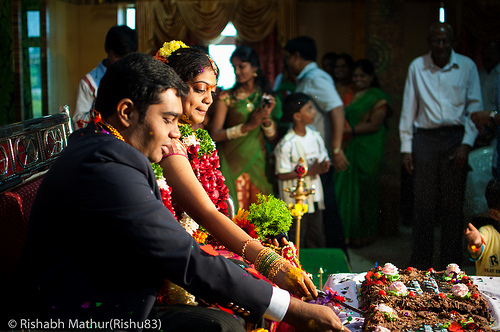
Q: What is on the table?
A: A cake.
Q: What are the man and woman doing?
A: Cutting the cake.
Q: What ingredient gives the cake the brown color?
A: Chocolate.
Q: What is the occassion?
A: A wedding.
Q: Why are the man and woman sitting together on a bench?
A: Because they are bride and groom.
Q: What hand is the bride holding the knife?
A: Right hand.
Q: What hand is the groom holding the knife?
A: Right hand.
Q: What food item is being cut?
A: A cake.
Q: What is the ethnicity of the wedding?
A: Indian.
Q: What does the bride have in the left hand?
A: Flowers.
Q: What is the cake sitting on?
A: A table.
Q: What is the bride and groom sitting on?
A: A bench.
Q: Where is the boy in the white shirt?
A: In the center of the photo in the background.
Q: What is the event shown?
A: A wedding.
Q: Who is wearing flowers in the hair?
A: The bride.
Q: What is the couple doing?
A: Cutting a cake.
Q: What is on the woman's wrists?
A: Bracelets.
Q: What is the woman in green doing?
A: Clapping.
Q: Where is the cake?
A: In front of the couple.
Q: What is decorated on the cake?
A: Flowers.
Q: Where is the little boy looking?
A: To the right.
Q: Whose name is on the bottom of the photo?
A: Rishabah Mathur.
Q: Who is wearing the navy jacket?
A: The groom.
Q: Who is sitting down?
A: Bride and groom.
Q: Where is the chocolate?
A: On the cake.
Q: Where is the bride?
A: Next to the groom.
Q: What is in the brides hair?
A: Flowers.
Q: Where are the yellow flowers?
A: Ladies hair.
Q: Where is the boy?
A: Next to the lady.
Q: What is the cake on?
A: A table.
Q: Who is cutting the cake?
A: The woman.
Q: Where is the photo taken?
A: Wedding reception.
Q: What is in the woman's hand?
A: A knife.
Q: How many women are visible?
A: Three.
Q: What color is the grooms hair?
A: Black.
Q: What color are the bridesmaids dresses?
A: Green.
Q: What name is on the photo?
A: Rishabh Mathur.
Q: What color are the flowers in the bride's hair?
A: Yellow.